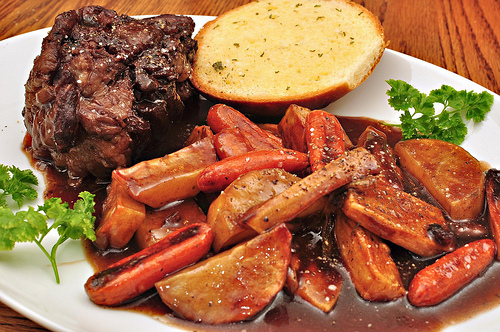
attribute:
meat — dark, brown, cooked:
[56, 37, 162, 149]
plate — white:
[414, 55, 448, 88]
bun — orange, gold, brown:
[257, 19, 337, 76]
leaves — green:
[399, 80, 458, 131]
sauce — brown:
[326, 279, 381, 323]